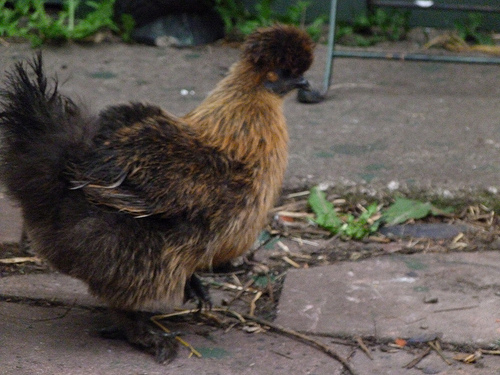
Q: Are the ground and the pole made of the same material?
A: No, the ground is made of concrete and the pole is made of metal.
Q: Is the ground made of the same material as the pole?
A: No, the ground is made of concrete and the pole is made of metal.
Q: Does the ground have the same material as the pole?
A: No, the ground is made of concrete and the pole is made of metal.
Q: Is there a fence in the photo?
A: No, there are no fences.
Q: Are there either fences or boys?
A: No, there are no fences or boys.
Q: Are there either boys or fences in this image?
A: No, there are no fences or boys.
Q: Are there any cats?
A: No, there are no cats.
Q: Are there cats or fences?
A: No, there are no cats or fences.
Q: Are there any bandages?
A: No, there are no bandages.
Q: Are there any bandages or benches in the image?
A: No, there are no bandages or benches.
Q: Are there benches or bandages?
A: No, there are no bandages or benches.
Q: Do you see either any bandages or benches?
A: No, there are no bandages or benches.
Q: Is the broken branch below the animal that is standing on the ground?
A: Yes, the branch is below the chicken.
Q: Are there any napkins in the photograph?
A: No, there are no napkins.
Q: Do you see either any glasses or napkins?
A: No, there are no napkins or glasses.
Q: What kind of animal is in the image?
A: The animal is chicken.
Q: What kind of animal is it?
A: The animal is chicken.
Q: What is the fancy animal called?
A: The animal is chicken.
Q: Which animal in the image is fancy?
A: The animal is chicken.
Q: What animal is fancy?
A: The animal is chicken.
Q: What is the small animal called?
A: The animal is chicken.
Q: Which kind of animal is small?
A: The animal is chicken.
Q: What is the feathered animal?
A: The animal is chicken.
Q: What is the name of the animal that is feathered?
A: The animal is chicken.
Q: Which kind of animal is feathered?
A: The animal is chicken.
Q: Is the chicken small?
A: Yes, the chicken is small.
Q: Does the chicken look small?
A: Yes, the chicken is small.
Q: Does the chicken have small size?
A: Yes, the chicken is small.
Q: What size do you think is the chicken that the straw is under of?
A: The chicken is small.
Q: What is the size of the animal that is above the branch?
A: The chicken is small.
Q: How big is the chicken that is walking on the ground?
A: The chicken is small.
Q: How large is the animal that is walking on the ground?
A: The chicken is small.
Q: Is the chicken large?
A: No, the chicken is small.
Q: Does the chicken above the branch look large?
A: No, the chicken is small.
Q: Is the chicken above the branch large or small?
A: The chicken is small.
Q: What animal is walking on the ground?
A: The chicken is walking on the ground.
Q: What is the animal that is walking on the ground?
A: The animal is chicken.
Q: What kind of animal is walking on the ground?
A: The animal is chicken.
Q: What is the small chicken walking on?
A: The chicken is walking on the ground.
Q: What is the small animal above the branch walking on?
A: The chicken is walking on the ground.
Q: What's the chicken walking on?
A: The chicken is walking on the ground.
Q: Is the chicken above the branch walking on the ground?
A: Yes, the chicken is walking on the ground.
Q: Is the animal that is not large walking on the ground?
A: Yes, the chicken is walking on the ground.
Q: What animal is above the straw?
A: The animal is chicken.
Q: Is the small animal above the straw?
A: Yes, the chicken is above the straw.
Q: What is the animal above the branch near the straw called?
A: The animal is chicken.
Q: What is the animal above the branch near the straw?
A: The animal is chicken.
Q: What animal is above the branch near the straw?
A: The animal is chicken.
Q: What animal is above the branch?
A: The animal is chicken.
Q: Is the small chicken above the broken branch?
A: Yes, the chicken is above the branch.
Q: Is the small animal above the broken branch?
A: Yes, the chicken is above the branch.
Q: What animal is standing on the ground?
A: The animal is chicken.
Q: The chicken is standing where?
A: The chicken is standing on the ground.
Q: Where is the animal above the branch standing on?
A: The chicken is standing on the ground.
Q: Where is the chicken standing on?
A: The chicken is standing on the ground.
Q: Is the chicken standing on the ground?
A: Yes, the chicken is standing on the ground.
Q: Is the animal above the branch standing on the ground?
A: Yes, the chicken is standing on the ground.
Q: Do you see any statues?
A: No, there are no statues.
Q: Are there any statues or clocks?
A: No, there are no statues or clocks.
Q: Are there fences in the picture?
A: No, there are no fences.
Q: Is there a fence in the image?
A: No, there are no fences.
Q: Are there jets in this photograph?
A: No, there are no jets.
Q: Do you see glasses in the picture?
A: No, there are no glasses.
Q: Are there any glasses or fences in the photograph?
A: No, there are no glasses or fences.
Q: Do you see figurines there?
A: No, there are no figurines.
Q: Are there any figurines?
A: No, there are no figurines.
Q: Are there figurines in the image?
A: No, there are no figurines.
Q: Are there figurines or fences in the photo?
A: No, there are no figurines or fences.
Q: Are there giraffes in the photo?
A: No, there are no giraffes.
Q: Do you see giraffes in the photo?
A: No, there are no giraffes.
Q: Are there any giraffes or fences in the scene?
A: No, there are no giraffes or fences.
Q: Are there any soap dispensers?
A: No, there are no soap dispensers.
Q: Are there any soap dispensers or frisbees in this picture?
A: No, there are no soap dispensers or frisbees.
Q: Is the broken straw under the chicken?
A: Yes, the straw is under the chicken.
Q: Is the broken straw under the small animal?
A: Yes, the straw is under the chicken.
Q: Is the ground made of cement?
A: Yes, the ground is made of cement.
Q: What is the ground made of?
A: The ground is made of concrete.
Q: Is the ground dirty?
A: Yes, the ground is dirty.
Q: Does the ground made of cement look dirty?
A: Yes, the ground is dirty.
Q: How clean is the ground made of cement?
A: The ground is dirty.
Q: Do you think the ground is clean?
A: No, the ground is dirty.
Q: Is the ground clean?
A: No, the ground is dirty.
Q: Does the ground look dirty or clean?
A: The ground is dirty.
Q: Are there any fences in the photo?
A: No, there are no fences.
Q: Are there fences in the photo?
A: No, there are no fences.